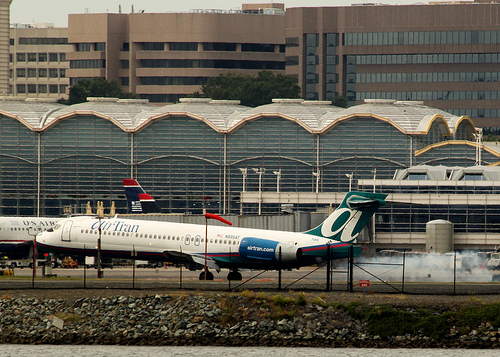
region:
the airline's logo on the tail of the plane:
[297, 188, 389, 245]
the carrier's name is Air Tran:
[86, 215, 146, 242]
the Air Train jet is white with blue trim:
[29, 188, 386, 282]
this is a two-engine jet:
[236, 231, 311, 268]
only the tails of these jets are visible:
[120, 175, 165, 215]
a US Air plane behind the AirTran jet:
[1, 213, 76, 247]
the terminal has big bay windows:
[353, 193, 497, 246]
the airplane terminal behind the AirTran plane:
[236, 158, 499, 259]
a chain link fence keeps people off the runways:
[0, 236, 499, 297]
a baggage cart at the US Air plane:
[1, 251, 65, 269]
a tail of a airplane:
[304, 183, 388, 238]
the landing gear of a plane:
[196, 265, 214, 282]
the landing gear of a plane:
[224, 267, 245, 283]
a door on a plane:
[58, 216, 74, 242]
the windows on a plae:
[78, 225, 240, 247]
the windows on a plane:
[7, 223, 50, 233]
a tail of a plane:
[119, 174, 156, 216]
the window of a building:
[13, 48, 30, 64]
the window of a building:
[25, 50, 40, 65]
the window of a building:
[34, 65, 50, 79]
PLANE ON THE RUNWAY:
[5, 190, 361, 279]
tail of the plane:
[322, 189, 364, 249]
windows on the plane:
[135, 225, 232, 246]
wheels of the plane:
[152, 272, 252, 280]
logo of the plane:
[88, 213, 150, 236]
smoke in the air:
[387, 253, 482, 273]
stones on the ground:
[120, 304, 237, 322]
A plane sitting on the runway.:
[36, 195, 376, 275]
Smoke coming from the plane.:
[353, 245, 490, 280]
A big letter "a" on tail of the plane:
[311, 190, 380, 247]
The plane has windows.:
[136, 223, 238, 250]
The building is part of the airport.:
[56, 102, 490, 222]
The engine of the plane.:
[236, 231, 303, 262]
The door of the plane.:
[54, 211, 76, 246]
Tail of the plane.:
[319, 187, 392, 242]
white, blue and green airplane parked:
[22, 187, 393, 287]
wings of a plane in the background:
[115, 170, 157, 212]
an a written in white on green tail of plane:
[311, 189, 371, 248]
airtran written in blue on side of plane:
[86, 214, 144, 235]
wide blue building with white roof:
[0, 89, 496, 211]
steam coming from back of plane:
[326, 242, 496, 299]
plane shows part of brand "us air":
[0, 213, 87, 242]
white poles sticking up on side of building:
[226, 152, 379, 214]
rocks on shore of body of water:
[0, 287, 490, 355]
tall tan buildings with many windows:
[0, 2, 497, 134]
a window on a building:
[347, 30, 351, 50]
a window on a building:
[351, 32, 356, 47]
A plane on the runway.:
[45, 194, 375, 291]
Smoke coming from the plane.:
[358, 236, 497, 284]